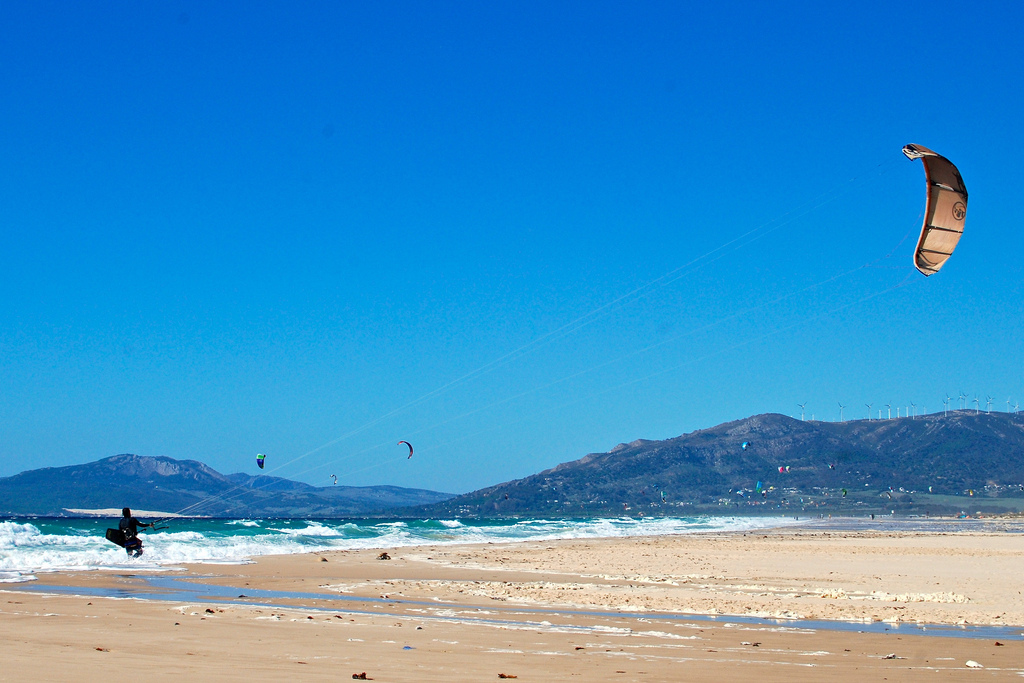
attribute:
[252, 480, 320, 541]
leaves — green 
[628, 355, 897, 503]
grass — green 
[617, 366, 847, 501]
grass — green 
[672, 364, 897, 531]
grass — green 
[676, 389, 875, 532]
grass — green 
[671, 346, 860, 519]
grass — green 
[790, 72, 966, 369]
kite — large , brown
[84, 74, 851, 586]
sky — large , wide , blue 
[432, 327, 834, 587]
mountains — large 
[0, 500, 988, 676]
beach — tan, large, wide, open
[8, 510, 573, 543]
water — large, white, green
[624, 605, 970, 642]
stream — blue water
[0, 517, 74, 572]
wave — white, small, crashing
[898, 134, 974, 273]
kite — large, brown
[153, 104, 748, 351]
sky — blue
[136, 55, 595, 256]
sky — blue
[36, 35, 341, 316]
sky — blue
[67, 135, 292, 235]
sky — blue